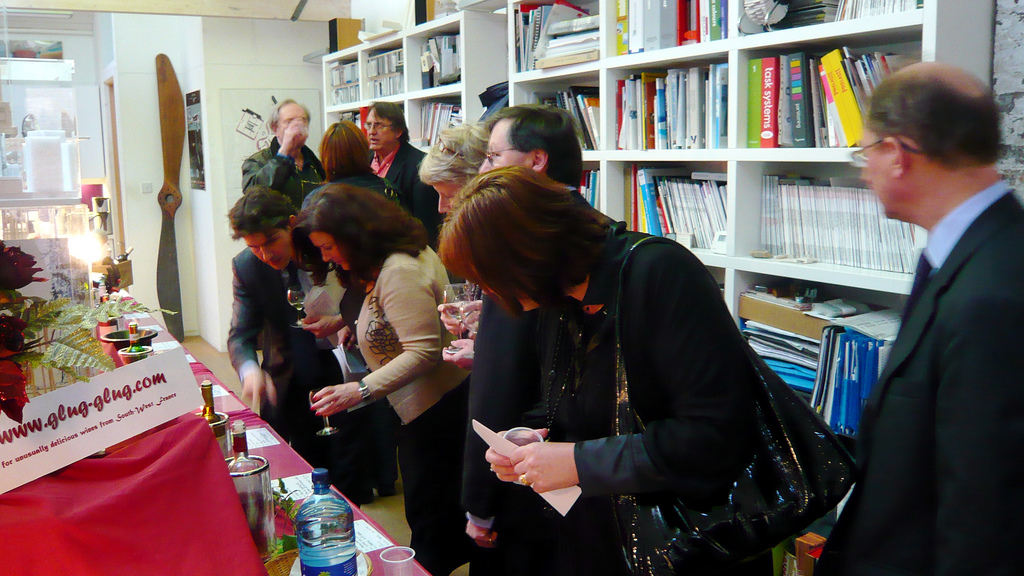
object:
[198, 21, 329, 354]
wall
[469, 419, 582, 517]
white paper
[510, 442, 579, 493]
hand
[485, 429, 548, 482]
hand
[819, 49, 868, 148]
binder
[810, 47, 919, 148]
book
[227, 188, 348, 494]
man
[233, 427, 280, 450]
paper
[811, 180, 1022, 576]
man suit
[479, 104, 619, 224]
man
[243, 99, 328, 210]
man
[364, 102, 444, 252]
man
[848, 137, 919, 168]
glasses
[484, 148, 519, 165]
glasses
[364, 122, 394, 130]
glasses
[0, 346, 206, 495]
sign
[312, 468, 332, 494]
cap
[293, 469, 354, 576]
water bottle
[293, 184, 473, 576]
woman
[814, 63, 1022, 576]
man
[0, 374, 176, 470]
address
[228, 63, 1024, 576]
people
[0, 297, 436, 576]
table